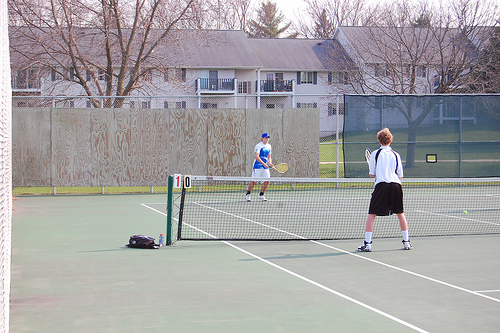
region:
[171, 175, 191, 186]
numbers for keeping score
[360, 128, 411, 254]
tennis player wearing black and white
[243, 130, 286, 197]
tennis player wearing blue and white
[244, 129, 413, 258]
two tennis players outside on the court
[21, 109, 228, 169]
wooden boards attached to the fence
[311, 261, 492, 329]
white lines on the tennis court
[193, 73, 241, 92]
outdoor deck on the building in the background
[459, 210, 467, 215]
green tennis ball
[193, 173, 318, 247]
net between the two tennis players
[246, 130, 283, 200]
tennis player wearing a blue hat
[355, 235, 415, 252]
Boy wearing shoes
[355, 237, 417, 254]
Boy is wearing shoes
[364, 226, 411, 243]
Boy wearing socks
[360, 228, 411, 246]
Boy is wearing white socks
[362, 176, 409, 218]
Boy wearing shorts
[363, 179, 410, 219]
Boy is wearing shorts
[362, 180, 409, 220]
Boy wearing black shorts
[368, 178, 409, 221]
Boy is wearing black shorts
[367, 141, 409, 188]
Boy wearing a shirt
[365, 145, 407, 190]
Boy is wearing a shirt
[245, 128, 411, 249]
two men playing tennis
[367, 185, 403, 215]
man wearing black shorts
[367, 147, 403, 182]
white and black top man is wearing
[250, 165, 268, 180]
white shorts man is wearing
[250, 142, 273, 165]
blue and white top man is wearing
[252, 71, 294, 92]
deck on building in the distance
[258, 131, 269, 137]
boy wearing a blue cap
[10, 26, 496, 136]
town homes in the distance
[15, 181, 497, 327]
green and white tennis court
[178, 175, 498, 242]
black and white tennis net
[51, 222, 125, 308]
tennis court that is fading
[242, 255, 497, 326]
white lines painted for boundaries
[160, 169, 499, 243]
net for boundaries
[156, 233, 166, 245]
water bottle to quench thirst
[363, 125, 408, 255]
boy in tennis gear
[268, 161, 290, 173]
racquet for a game of tennis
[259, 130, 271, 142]
hat to protect eyes from sun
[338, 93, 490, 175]
high fence to block of tennis court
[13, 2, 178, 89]
trees without leaves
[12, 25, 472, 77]
buildings for people to live in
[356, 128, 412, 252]
A male playing tennis.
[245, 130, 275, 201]
A man wearing blue and white.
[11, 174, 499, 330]
A green and white tennis court.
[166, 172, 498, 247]
A tennis court net.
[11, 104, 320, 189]
A wall of wood.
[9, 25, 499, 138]
A large white building.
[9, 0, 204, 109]
A large dormant tree.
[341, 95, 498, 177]
Dark green net fencing.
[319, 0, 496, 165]
A medium dormant tree.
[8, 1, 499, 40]
A bright clear sky.